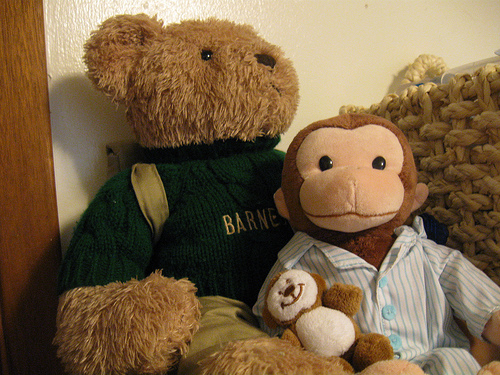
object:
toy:
[81, 12, 297, 375]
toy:
[294, 151, 403, 287]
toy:
[282, 288, 348, 349]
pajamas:
[299, 242, 499, 342]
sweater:
[60, 146, 296, 296]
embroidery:
[222, 209, 278, 236]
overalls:
[131, 163, 170, 230]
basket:
[429, 90, 498, 210]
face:
[297, 125, 405, 234]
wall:
[301, 5, 446, 54]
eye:
[201, 50, 212, 60]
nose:
[258, 54, 276, 66]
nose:
[352, 188, 359, 193]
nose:
[284, 285, 294, 295]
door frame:
[7, 0, 45, 245]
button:
[382, 305, 397, 319]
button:
[379, 277, 387, 286]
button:
[389, 335, 401, 348]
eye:
[319, 155, 333, 168]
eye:
[373, 156, 386, 169]